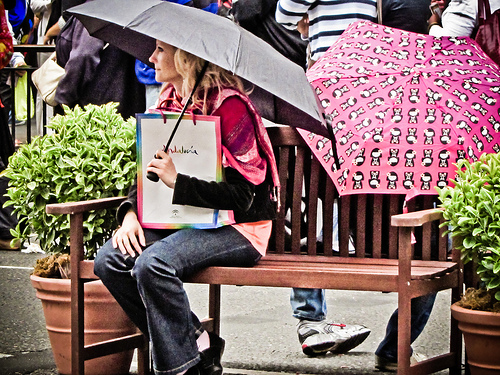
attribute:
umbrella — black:
[218, 61, 302, 106]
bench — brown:
[41, 119, 480, 372]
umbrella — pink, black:
[285, 15, 481, 206]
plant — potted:
[4, 97, 159, 372]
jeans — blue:
[88, 215, 270, 372]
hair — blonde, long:
[161, 38, 260, 116]